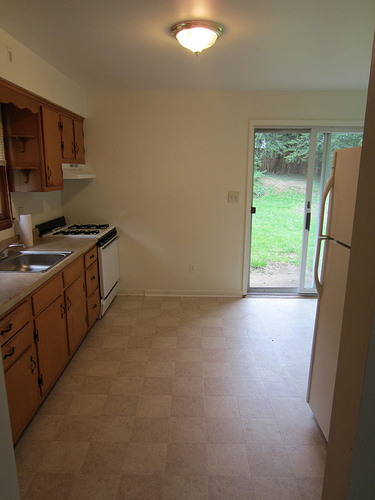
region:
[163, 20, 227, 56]
a ceiling light fixture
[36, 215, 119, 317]
a black and white oven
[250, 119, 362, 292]
part of a sliding door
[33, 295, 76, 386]
a wooden cabinet door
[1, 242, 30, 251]
part of a sink faucet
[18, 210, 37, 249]
a roll of paper towels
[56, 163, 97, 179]
a white range hood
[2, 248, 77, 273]
a silver sink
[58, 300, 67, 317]
a cabinet handle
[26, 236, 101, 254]
a beige kitchen counter top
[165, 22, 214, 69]
white light on ceiling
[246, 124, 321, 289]
screen door is open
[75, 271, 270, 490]
tan and brown floor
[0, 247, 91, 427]
brown and black cabinets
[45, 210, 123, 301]
black and white range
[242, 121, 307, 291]
white frame on door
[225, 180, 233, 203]
cream colored light switch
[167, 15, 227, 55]
circular light on ceiling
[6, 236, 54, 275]
stainless steel sink on counter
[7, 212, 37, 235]
circular paper towel holder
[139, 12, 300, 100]
a light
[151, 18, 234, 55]
a light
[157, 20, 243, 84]
a light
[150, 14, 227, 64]
a light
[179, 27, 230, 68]
Light fixture on ceiling.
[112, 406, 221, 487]
Brown tiles on floor.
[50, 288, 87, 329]
Black handles on cabinets.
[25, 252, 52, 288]
Sink is silver inside.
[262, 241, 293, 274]
Green grass outside the door.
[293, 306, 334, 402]
White refrigerator in room.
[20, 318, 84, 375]
Brown wood cabinets in room.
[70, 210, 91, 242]
Black burners on the stove.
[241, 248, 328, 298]
Sliding glass door leading outside.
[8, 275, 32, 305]
Light brown counter tops in kitchen.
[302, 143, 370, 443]
the white refrigerator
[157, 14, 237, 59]
the light on the ceiling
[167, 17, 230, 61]
the light is on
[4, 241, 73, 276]
the faucet over the sink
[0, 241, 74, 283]
the sink in the counter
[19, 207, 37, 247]
the paper towels on the counter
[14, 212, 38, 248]
the paper towels are white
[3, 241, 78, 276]
the sink is metal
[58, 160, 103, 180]
the hood over the range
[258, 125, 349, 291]
the sliding door is open